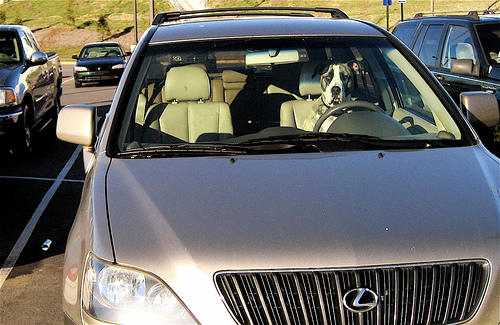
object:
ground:
[0, 65, 126, 324]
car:
[72, 42, 131, 85]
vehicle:
[57, 6, 499, 322]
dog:
[311, 59, 373, 132]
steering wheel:
[313, 102, 391, 136]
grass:
[0, 0, 500, 64]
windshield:
[105, 34, 480, 159]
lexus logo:
[341, 287, 380, 314]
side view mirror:
[55, 104, 99, 148]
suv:
[387, 10, 500, 155]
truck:
[1, 24, 63, 170]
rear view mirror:
[243, 49, 302, 65]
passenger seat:
[143, 63, 233, 143]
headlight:
[80, 252, 202, 325]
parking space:
[0, 114, 106, 182]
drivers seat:
[280, 64, 330, 130]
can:
[40, 239, 53, 251]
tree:
[96, 13, 112, 42]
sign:
[381, 0, 392, 5]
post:
[386, 0, 389, 31]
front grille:
[213, 39, 493, 256]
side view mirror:
[459, 90, 500, 127]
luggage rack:
[149, 4, 349, 25]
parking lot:
[0, 64, 129, 215]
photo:
[0, 1, 499, 324]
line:
[0, 117, 101, 290]